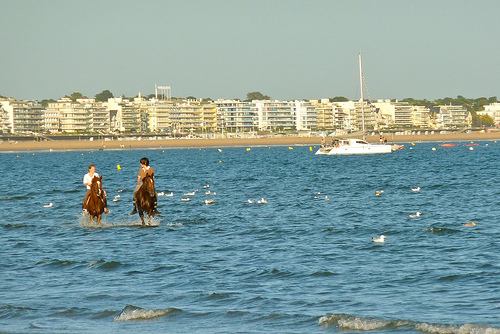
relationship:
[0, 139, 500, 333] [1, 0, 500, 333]
water at beach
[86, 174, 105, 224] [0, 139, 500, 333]
horse in water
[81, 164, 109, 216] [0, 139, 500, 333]
person in water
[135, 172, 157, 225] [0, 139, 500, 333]
horse on water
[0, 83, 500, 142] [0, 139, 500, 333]
buildings beyond water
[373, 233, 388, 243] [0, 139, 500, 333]
bird on water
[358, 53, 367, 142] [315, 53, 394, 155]
pole on boat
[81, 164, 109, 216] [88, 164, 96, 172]
person has hair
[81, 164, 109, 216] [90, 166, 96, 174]
person has a face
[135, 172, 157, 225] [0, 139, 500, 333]
horse in water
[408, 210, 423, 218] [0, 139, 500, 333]
bird on water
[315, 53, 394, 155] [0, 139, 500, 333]
boat on water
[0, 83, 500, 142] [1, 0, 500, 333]
buildings near beach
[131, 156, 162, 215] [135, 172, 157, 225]
person on horse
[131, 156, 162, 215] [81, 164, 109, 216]
person looking at other person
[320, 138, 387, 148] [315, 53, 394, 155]
people on boat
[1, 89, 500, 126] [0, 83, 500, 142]
trees behind buildings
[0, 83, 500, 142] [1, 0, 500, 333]
buildings at beach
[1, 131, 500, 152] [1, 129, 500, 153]
sand on shore